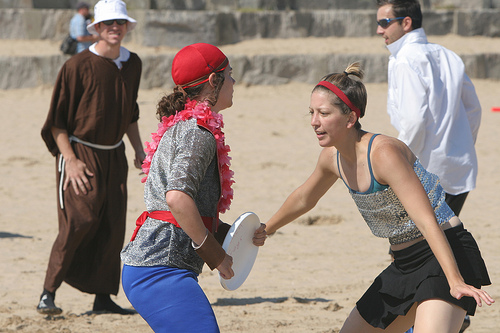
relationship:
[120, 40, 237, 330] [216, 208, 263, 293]
girl holding frisbee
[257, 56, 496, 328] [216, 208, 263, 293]
girl blocking frisbee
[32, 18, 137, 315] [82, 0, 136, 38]
guy in hat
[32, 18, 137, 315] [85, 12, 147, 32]
guy in sunglass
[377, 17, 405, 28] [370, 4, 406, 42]
sunglasses on face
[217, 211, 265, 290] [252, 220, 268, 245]
frisbee in hand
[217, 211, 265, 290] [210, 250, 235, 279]
frisbee in hand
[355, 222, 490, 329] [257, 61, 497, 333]
black skirt worn by girl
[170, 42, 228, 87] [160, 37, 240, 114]
red cap on head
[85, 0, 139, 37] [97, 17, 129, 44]
hat on head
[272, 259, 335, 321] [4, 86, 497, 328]
sand on beach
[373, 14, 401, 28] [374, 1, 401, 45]
sunglasses on face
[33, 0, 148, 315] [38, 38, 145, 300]
guy dressed in dress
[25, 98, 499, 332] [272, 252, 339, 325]
ground with sand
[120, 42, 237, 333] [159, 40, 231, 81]
girl wearing red cap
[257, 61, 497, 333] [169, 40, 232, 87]
girl wearing cap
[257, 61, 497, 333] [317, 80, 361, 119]
girl wearing headband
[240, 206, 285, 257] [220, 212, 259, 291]
hands holding frisbee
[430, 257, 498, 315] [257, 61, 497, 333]
hand of girl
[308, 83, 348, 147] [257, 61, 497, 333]
face of girl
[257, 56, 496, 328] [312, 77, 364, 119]
girl wearing headband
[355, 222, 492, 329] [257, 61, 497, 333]
black skirt on girl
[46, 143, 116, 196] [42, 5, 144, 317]
hand of man